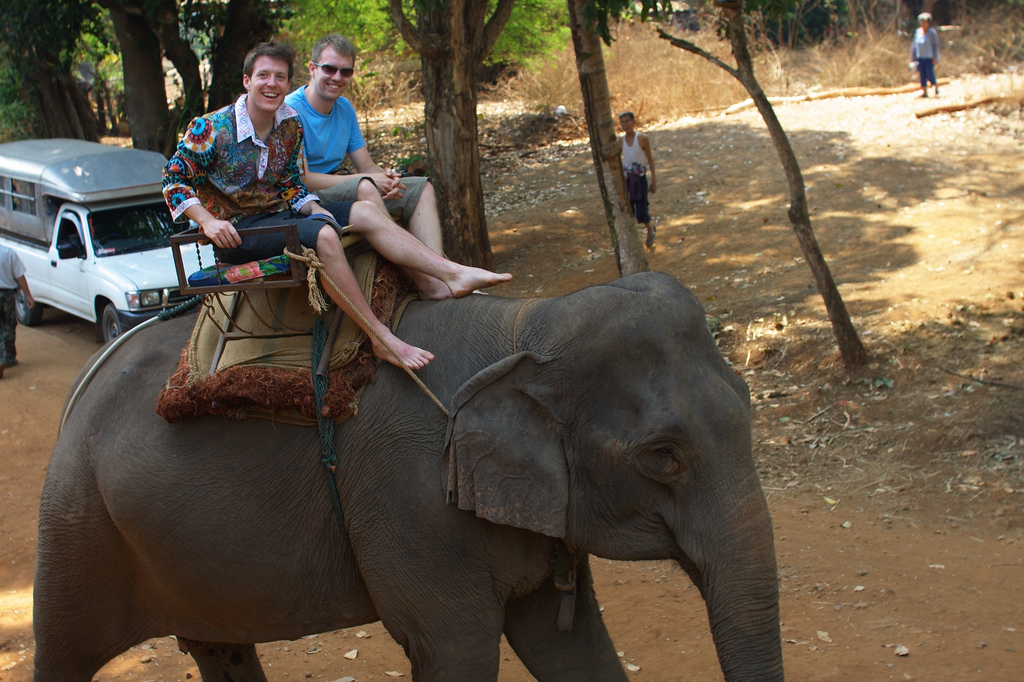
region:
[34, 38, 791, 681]
man is riding an elephant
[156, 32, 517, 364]
man is wearing a colorful shirt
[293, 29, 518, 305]
man is wearing a blue t-shirt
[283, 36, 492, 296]
man is wearing sunglasses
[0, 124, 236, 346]
silver camper shell on white truck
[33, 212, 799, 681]
seat on gray elephant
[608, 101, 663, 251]
man is wearing a white tank top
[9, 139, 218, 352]
windshield on white truck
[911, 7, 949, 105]
woman wearing blue capri pants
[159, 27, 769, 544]
two men sitting on a elephant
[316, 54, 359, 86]
a man wearing sunglasses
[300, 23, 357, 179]
a man wearing a blue shirt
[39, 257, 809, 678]
a grey elephant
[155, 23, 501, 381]
two men wearing shorts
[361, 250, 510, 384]
a man with bare feet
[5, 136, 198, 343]
a white truck with a camper on the back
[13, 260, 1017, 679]
a elephant walking on a dirt path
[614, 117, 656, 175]
a man wearing a white shirt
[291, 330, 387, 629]
a green rope tied around a elephants stomach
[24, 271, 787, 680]
big gray elephant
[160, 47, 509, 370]
boy wearing multicolored t-shirt on top of elephant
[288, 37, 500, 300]
man wearing light blue t-shirt on top of elephant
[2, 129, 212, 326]
gray and white van parked in the ground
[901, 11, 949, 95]
woman in the background wearing gray sweater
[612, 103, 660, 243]
woman wearing white t-shirt and black pants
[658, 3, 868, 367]
small thin brown stem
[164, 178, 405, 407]
brown saddle on top of elephant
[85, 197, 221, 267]
black windshield of white van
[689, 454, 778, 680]
gray large thick trunk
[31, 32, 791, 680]
two guys on an elephant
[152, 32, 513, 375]
the men are both barefoot sitting on the elephant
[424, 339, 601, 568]
the elephant has small ears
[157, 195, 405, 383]
a metal bench is strapped onto the elephant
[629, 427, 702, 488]
the eyes of the elephant are open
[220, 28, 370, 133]
the two men are smiling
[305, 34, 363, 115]
the person has sunglasses on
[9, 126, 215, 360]
a vehicle is parked behind the elephant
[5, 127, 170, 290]
there is a camper on the bed of the pick up truck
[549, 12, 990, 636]
people are standing around watching the elephant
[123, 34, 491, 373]
a pair of men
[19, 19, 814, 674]
the men are riding a horse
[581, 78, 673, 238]
person in the background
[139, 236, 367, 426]
fabric on the elephant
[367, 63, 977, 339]
shadow on the ground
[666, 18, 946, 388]
tilted trunk of a tree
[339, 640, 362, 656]
dead leaf on the ground by the elephant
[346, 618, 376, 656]
dead leaf on the ground by the elephant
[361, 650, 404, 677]
dead leaf on the ground by the elephant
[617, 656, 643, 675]
dead leaf on the ground by the elephant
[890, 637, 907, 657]
dead leaf on the ground by the elephant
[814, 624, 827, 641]
dead leaf on the ground by the elephant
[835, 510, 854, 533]
dead leaf on the ground by the elephant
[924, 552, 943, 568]
dead leaf on the ground by the elephant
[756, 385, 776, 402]
dead leaf on the ground by the elephant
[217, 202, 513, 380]
the mans legs below torso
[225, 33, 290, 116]
the mans head above shoulders